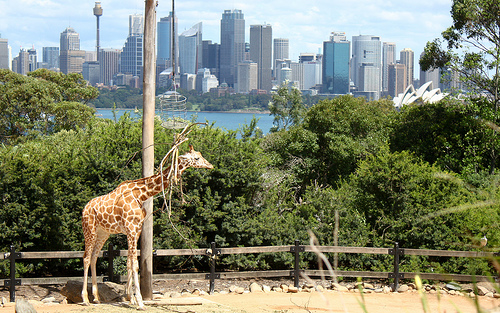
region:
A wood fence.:
[5, 231, 497, 308]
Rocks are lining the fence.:
[25, 275, 497, 305]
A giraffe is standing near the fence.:
[52, 130, 237, 310]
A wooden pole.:
[125, 0, 170, 297]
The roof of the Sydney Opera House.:
[385, 70, 455, 110]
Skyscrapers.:
[157, 5, 307, 110]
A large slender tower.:
[85, 0, 111, 55]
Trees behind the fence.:
[1, 80, 486, 300]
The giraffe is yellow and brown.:
[70, 140, 240, 307]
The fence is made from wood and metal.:
[197, 225, 408, 305]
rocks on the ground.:
[238, 284, 290, 294]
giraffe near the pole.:
[95, 189, 140, 236]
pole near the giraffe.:
[145, 59, 158, 165]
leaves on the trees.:
[333, 110, 368, 152]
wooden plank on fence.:
[227, 242, 285, 257]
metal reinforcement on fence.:
[292, 244, 303, 287]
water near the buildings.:
[213, 112, 250, 127]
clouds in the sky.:
[355, 5, 412, 31]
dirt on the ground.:
[295, 301, 361, 311]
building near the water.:
[222, 23, 242, 73]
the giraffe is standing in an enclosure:
[69, 143, 218, 308]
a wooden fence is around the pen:
[2, 232, 498, 302]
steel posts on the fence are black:
[285, 237, 408, 291]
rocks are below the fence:
[6, 280, 498, 302]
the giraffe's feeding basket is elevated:
[149, 88, 196, 152]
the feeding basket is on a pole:
[132, 0, 190, 310]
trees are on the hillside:
[6, 74, 499, 239]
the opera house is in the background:
[389, 75, 450, 113]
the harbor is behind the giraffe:
[15, 95, 327, 160]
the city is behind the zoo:
[6, 6, 497, 208]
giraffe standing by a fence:
[51, 120, 238, 310]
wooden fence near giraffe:
[169, 239, 485, 294]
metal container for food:
[157, 85, 196, 131]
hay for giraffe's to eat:
[154, 127, 187, 169]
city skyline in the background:
[169, 12, 414, 95]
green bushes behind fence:
[269, 134, 497, 213]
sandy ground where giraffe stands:
[217, 290, 405, 310]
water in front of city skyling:
[206, 113, 269, 125]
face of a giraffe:
[173, 142, 223, 185]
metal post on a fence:
[206, 241, 228, 288]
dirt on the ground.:
[248, 297, 270, 304]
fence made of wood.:
[240, 251, 290, 253]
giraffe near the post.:
[102, 192, 145, 224]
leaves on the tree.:
[262, 209, 289, 227]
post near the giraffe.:
[140, 80, 157, 157]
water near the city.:
[215, 112, 246, 124]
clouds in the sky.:
[276, 8, 313, 32]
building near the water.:
[328, 40, 348, 85]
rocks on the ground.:
[246, 282, 277, 293]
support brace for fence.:
[392, 247, 397, 281]